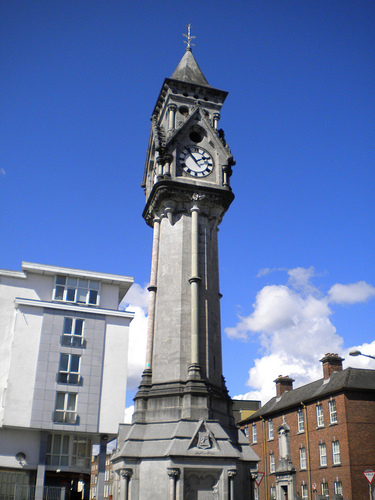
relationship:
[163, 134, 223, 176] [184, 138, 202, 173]
clock says 1:54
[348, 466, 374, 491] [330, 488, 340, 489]
sign on street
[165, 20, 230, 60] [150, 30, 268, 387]
weather vane on clock tower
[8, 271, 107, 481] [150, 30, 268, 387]
building behind clock tower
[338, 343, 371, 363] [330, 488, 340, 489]
street light over street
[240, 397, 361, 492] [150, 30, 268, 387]
building behind clock tower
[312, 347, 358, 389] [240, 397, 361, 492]
chimney on building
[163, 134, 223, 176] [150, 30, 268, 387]
clock on clock tower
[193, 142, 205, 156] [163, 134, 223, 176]
numbers on clock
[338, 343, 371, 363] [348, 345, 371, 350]
street light has top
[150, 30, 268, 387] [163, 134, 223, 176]
clock tower has many clock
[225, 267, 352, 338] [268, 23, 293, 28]
clouds in sky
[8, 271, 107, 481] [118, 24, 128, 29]
building in background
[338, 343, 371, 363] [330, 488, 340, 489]
street light on street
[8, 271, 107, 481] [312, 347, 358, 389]
building has chimney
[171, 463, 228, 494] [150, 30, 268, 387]
door on clock tower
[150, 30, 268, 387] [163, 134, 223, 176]
clock tower has clock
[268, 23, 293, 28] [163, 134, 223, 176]
sky near clock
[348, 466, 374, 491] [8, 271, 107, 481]
sign by building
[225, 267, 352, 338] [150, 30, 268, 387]
clouds by clock tower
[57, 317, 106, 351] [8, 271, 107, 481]
window in gray building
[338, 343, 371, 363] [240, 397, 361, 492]
street light by building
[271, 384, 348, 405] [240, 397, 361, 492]
roof on building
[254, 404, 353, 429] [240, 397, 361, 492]
gutter on building